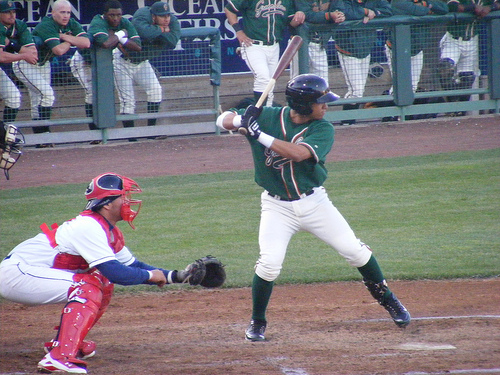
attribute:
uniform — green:
[211, 84, 396, 285]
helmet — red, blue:
[72, 158, 150, 234]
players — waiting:
[18, 2, 499, 139]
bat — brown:
[230, 23, 307, 146]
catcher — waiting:
[22, 151, 217, 367]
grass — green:
[6, 169, 491, 286]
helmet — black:
[277, 72, 348, 114]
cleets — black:
[243, 282, 427, 350]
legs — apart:
[206, 173, 441, 332]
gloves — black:
[231, 108, 276, 151]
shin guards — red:
[50, 262, 125, 374]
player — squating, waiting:
[1, 162, 179, 351]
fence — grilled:
[4, 2, 499, 162]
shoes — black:
[239, 295, 443, 358]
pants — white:
[227, 157, 391, 300]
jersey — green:
[222, 95, 347, 208]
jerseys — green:
[1, 6, 477, 40]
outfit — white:
[3, 193, 147, 343]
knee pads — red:
[45, 260, 130, 358]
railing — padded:
[13, 0, 497, 46]